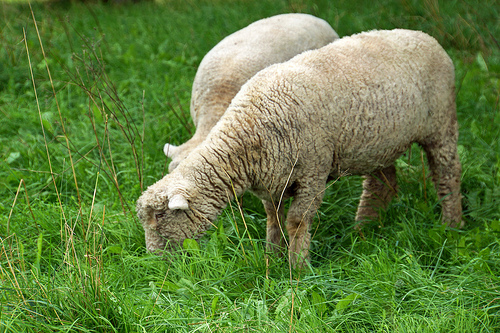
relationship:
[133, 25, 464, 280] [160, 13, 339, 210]
sheep in front of sheep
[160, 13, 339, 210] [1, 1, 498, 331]
sheep eating grass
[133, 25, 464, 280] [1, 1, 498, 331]
sheep eating grass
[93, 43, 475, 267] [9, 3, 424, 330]
sheep eating grass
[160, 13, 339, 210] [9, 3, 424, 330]
sheep eating grass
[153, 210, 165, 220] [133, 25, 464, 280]
eye on sheep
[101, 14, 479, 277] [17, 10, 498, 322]
sheep in field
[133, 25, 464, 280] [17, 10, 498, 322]
sheep in field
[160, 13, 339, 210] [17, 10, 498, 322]
sheep in field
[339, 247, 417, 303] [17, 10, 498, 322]
grass in field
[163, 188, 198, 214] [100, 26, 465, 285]
ear attached to sheep